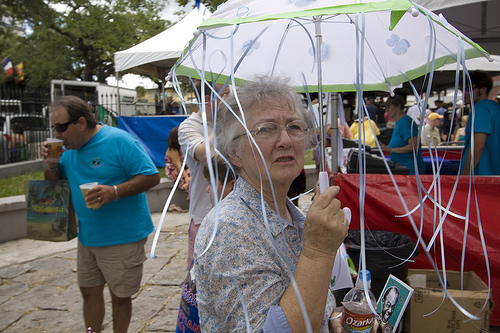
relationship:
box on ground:
[395, 263, 495, 330] [8, 200, 201, 330]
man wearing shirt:
[15, 97, 163, 331] [53, 127, 164, 251]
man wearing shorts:
[32, 97, 161, 331] [71, 232, 148, 297]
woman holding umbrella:
[182, 70, 386, 329] [171, 2, 492, 108]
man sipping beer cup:
[32, 97, 161, 331] [45, 138, 65, 166]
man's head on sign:
[382, 285, 397, 323] [376, 270, 418, 330]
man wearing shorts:
[32, 97, 161, 331] [71, 237, 147, 301]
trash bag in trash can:
[352, 225, 415, 257] [344, 225, 421, 305]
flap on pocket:
[127, 250, 152, 271] [123, 249, 152, 296]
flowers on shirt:
[226, 243, 254, 277] [184, 180, 307, 330]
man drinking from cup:
[32, 97, 161, 331] [46, 135, 64, 160]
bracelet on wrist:
[108, 180, 127, 207] [18, 77, 181, 330]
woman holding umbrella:
[182, 82, 368, 330] [169, 3, 473, 135]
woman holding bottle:
[182, 82, 368, 330] [336, 268, 372, 329]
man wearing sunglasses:
[32, 97, 161, 331] [43, 111, 85, 135]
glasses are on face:
[43, 109, 83, 136] [29, 92, 167, 331]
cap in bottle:
[342, 263, 367, 283] [333, 266, 373, 331]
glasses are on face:
[228, 116, 309, 145] [234, 84, 305, 183]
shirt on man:
[36, 122, 161, 245] [32, 97, 161, 331]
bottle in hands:
[336, 264, 381, 331] [326, 287, 395, 330]